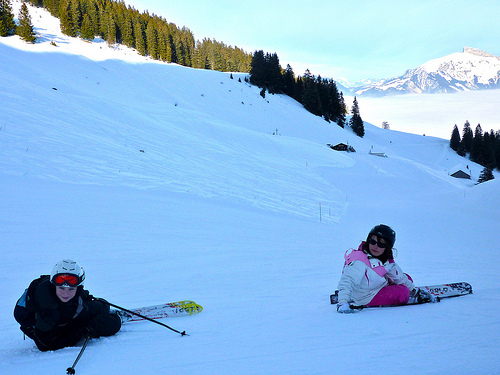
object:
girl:
[327, 218, 484, 316]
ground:
[0, 195, 500, 375]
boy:
[13, 259, 132, 353]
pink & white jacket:
[335, 251, 403, 309]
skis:
[426, 283, 474, 309]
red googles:
[48, 273, 84, 284]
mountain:
[378, 38, 496, 93]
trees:
[144, 10, 160, 60]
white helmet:
[36, 260, 95, 273]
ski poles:
[111, 293, 189, 348]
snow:
[106, 74, 164, 93]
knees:
[394, 284, 416, 303]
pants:
[364, 284, 424, 306]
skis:
[119, 302, 205, 324]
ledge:
[458, 48, 490, 60]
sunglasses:
[364, 237, 390, 247]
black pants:
[85, 300, 121, 338]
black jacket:
[28, 274, 81, 338]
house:
[446, 158, 476, 181]